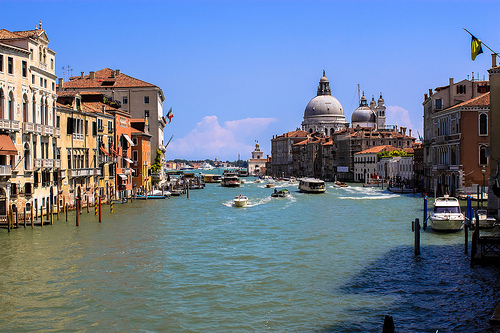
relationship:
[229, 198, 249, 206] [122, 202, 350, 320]
boat speeding down river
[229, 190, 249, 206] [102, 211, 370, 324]
boat moving on canal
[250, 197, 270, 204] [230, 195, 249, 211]
wake behind boat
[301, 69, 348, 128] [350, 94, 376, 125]
dome to left of dome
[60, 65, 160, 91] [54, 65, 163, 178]
roof on top of building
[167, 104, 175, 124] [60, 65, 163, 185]
flags hanging from building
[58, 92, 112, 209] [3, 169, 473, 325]
building next to canal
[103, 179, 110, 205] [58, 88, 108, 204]
pole in front of building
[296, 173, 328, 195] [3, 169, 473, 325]
vaporetto floating on canal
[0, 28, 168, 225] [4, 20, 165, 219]
row of houses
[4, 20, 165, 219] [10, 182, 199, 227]
houses on waterfront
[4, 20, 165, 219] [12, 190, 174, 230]
houses on waterfront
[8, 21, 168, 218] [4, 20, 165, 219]
row of houses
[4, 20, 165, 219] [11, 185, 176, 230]
houses on waterfront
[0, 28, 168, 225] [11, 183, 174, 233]
row on waterfront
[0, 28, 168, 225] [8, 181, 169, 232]
row on waterfront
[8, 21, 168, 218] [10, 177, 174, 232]
row on waterfront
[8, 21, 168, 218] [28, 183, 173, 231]
row on waterfront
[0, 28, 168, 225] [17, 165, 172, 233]
row on waterfront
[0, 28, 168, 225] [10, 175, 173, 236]
row on waterfront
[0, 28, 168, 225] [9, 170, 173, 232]
row on waterfront